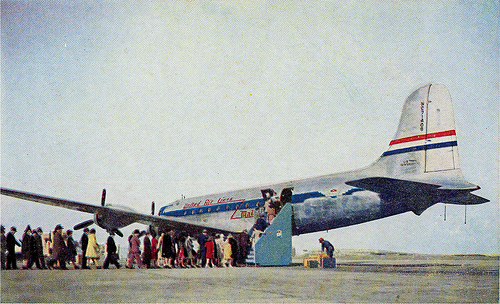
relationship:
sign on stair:
[270, 230, 285, 239] [238, 196, 302, 276]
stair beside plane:
[238, 196, 302, 276] [170, 69, 480, 265]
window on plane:
[212, 195, 234, 216] [170, 69, 480, 265]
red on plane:
[328, 183, 346, 191] [170, 69, 480, 265]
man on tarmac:
[195, 220, 214, 238] [197, 222, 215, 246]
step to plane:
[246, 242, 266, 260] [170, 69, 480, 265]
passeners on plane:
[242, 170, 270, 234] [170, 69, 480, 265]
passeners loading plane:
[242, 170, 270, 234] [170, 69, 480, 265]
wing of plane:
[22, 170, 135, 227] [170, 69, 480, 265]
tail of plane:
[423, 126, 455, 144] [170, 69, 480, 265]